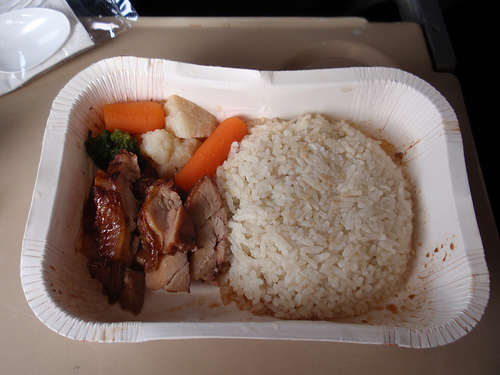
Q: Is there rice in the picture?
A: Yes, there is rice.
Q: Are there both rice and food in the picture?
A: Yes, there are both rice and food.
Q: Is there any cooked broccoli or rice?
A: Yes, there is cooked rice.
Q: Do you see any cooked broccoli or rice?
A: Yes, there is cooked rice.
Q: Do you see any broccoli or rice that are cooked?
A: Yes, the rice is cooked.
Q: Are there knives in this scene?
A: No, there are no knives.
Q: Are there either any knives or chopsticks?
A: No, there are no knives or chopsticks.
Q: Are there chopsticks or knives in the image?
A: No, there are no knives or chopsticks.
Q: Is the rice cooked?
A: Yes, the rice is cooked.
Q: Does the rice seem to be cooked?
A: Yes, the rice is cooked.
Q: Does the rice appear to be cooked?
A: Yes, the rice is cooked.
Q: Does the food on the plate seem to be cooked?
A: Yes, the rice is cooked.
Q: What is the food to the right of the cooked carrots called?
A: The food is rice.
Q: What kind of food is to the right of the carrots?
A: The food is rice.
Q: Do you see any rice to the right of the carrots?
A: Yes, there is rice to the right of the carrots.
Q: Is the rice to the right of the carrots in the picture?
A: Yes, the rice is to the right of the carrots.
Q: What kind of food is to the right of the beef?
A: The food is rice.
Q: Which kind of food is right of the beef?
A: The food is rice.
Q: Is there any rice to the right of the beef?
A: Yes, there is rice to the right of the beef.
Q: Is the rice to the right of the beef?
A: Yes, the rice is to the right of the beef.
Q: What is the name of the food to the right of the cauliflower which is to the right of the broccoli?
A: The food is rice.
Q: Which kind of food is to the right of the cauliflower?
A: The food is rice.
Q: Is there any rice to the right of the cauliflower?
A: Yes, there is rice to the right of the cauliflower.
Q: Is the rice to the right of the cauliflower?
A: Yes, the rice is to the right of the cauliflower.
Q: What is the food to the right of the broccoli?
A: The food is rice.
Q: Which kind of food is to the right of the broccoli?
A: The food is rice.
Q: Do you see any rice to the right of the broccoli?
A: Yes, there is rice to the right of the broccoli.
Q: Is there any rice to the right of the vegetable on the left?
A: Yes, there is rice to the right of the broccoli.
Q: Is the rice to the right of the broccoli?
A: Yes, the rice is to the right of the broccoli.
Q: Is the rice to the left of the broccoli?
A: No, the rice is to the right of the broccoli.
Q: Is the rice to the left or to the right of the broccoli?
A: The rice is to the right of the broccoli.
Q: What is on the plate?
A: The rice is on the plate.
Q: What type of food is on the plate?
A: The food is rice.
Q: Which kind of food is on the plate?
A: The food is rice.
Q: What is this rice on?
A: The rice is on the plate.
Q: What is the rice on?
A: The rice is on the plate.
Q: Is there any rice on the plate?
A: Yes, there is rice on the plate.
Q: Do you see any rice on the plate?
A: Yes, there is rice on the plate.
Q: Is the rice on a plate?
A: Yes, the rice is on a plate.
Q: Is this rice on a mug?
A: No, the rice is on a plate.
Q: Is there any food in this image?
A: Yes, there is food.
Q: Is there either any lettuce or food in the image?
A: Yes, there is food.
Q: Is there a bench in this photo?
A: No, there are no benches.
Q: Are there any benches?
A: No, there are no benches.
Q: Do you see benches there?
A: No, there are no benches.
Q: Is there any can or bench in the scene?
A: No, there are no benches or cans.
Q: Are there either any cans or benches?
A: No, there are no benches or cans.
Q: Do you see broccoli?
A: Yes, there is broccoli.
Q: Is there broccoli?
A: Yes, there is broccoli.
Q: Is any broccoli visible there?
A: Yes, there is broccoli.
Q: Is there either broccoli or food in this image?
A: Yes, there is broccoli.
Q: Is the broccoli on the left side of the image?
A: Yes, the broccoli is on the left of the image.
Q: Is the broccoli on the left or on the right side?
A: The broccoli is on the left of the image.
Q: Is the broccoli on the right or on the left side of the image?
A: The broccoli is on the left of the image.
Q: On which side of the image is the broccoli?
A: The broccoli is on the left of the image.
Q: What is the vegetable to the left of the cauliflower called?
A: The vegetable is broccoli.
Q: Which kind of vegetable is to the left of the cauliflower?
A: The vegetable is broccoli.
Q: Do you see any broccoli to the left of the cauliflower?
A: Yes, there is broccoli to the left of the cauliflower.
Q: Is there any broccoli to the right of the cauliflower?
A: No, the broccoli is to the left of the cauliflower.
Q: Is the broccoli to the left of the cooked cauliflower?
A: Yes, the broccoli is to the left of the cauliflower.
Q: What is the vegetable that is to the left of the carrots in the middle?
A: The vegetable is broccoli.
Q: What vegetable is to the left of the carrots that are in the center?
A: The vegetable is broccoli.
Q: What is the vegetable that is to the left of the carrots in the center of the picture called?
A: The vegetable is broccoli.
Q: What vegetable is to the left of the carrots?
A: The vegetable is broccoli.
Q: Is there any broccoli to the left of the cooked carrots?
A: Yes, there is broccoli to the left of the carrots.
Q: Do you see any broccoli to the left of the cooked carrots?
A: Yes, there is broccoli to the left of the carrots.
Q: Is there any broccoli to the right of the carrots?
A: No, the broccoli is to the left of the carrots.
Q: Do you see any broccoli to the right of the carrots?
A: No, the broccoli is to the left of the carrots.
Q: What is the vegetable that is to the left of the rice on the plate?
A: The vegetable is broccoli.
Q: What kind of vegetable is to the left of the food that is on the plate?
A: The vegetable is broccoli.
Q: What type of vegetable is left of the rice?
A: The vegetable is broccoli.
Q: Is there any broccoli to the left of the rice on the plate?
A: Yes, there is broccoli to the left of the rice.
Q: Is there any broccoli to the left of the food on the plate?
A: Yes, there is broccoli to the left of the rice.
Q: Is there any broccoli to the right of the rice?
A: No, the broccoli is to the left of the rice.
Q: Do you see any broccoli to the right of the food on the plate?
A: No, the broccoli is to the left of the rice.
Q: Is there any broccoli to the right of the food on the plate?
A: No, the broccoli is to the left of the rice.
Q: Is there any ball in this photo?
A: No, there are no balls.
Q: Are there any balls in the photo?
A: No, there are no balls.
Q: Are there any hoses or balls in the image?
A: No, there are no balls or hoses.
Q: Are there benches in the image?
A: No, there are no benches.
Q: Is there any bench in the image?
A: No, there are no benches.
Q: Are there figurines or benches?
A: No, there are no benches or figurines.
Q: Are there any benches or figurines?
A: No, there are no benches or figurines.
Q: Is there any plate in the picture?
A: Yes, there is a plate.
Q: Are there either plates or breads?
A: Yes, there is a plate.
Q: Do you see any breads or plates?
A: Yes, there is a plate.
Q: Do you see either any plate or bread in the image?
A: Yes, there is a plate.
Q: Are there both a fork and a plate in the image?
A: No, there is a plate but no forks.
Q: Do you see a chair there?
A: No, there are no chairs.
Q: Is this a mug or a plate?
A: This is a plate.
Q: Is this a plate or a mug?
A: This is a plate.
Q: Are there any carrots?
A: Yes, there are carrots.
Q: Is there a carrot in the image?
A: Yes, there are carrots.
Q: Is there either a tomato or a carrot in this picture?
A: Yes, there are carrots.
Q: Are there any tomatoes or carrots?
A: Yes, there are carrots.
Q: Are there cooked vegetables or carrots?
A: Yes, there are cooked carrots.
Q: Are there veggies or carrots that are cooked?
A: Yes, the carrots are cooked.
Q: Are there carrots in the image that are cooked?
A: Yes, there are cooked carrots.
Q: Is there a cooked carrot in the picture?
A: Yes, there are cooked carrots.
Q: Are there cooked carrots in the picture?
A: Yes, there are cooked carrots.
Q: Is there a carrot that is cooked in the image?
A: Yes, there are cooked carrots.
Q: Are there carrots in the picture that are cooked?
A: Yes, there are carrots that are cooked.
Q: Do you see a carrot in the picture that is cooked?
A: Yes, there are carrots that are cooked.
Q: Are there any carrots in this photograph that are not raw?
A: Yes, there are cooked carrots.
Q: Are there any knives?
A: No, there are no knives.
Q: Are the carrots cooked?
A: Yes, the carrots are cooked.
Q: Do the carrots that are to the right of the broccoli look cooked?
A: Yes, the carrots are cooked.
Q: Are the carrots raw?
A: No, the carrots are cooked.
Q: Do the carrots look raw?
A: No, the carrots are cooked.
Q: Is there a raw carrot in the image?
A: No, there are carrots but they are cooked.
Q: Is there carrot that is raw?
A: No, there are carrots but they are cooked.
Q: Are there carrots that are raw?
A: No, there are carrots but they are cooked.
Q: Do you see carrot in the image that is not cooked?
A: No, there are carrots but they are cooked.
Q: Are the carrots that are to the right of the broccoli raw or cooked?
A: The carrots are cooked.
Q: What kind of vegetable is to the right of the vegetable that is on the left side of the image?
A: The vegetables are carrots.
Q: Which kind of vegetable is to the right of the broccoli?
A: The vegetables are carrots.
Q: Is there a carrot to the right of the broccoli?
A: Yes, there are carrots to the right of the broccoli.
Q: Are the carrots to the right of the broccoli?
A: Yes, the carrots are to the right of the broccoli.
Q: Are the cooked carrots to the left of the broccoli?
A: No, the carrots are to the right of the broccoli.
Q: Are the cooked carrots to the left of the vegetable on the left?
A: No, the carrots are to the right of the broccoli.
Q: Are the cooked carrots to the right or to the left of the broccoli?
A: The carrots are to the right of the broccoli.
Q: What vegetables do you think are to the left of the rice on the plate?
A: The vegetables are carrots.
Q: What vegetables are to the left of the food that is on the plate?
A: The vegetables are carrots.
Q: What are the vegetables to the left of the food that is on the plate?
A: The vegetables are carrots.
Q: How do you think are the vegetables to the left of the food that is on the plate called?
A: The vegetables are carrots.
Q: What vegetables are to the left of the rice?
A: The vegetables are carrots.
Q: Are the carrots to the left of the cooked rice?
A: Yes, the carrots are to the left of the rice.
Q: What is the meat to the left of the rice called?
A: The meat is beef.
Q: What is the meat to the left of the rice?
A: The meat is beef.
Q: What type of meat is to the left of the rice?
A: The meat is beef.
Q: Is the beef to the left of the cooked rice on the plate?
A: Yes, the beef is to the left of the rice.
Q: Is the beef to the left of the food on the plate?
A: Yes, the beef is to the left of the rice.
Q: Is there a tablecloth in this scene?
A: No, there are no tablecloths.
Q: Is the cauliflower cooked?
A: Yes, the cauliflower is cooked.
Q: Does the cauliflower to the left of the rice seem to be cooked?
A: Yes, the cauliflower is cooked.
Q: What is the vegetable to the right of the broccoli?
A: The vegetable is cauliflower.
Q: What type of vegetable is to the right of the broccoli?
A: The vegetable is cauliflower.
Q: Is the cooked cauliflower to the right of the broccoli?
A: Yes, the cauliflower is to the right of the broccoli.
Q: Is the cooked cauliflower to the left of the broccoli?
A: No, the cauliflower is to the right of the broccoli.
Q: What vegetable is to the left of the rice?
A: The vegetable is cauliflower.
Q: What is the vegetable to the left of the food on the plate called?
A: The vegetable is cauliflower.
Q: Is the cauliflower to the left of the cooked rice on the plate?
A: Yes, the cauliflower is to the left of the rice.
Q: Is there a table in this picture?
A: Yes, there is a table.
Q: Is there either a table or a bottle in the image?
A: Yes, there is a table.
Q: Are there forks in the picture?
A: No, there are no forks.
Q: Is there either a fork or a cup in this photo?
A: No, there are no forks or cups.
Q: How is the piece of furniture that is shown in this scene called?
A: The piece of furniture is a table.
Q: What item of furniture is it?
A: The piece of furniture is a table.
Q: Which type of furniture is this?
A: This is a table.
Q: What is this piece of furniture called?
A: This is a table.